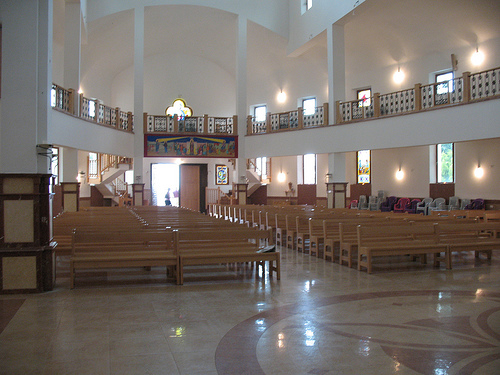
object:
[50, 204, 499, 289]
pew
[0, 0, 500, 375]
church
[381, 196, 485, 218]
chair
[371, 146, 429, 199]
wall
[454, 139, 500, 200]
wall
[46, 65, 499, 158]
balcony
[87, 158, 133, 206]
stairs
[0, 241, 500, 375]
floor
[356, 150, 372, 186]
window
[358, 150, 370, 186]
glass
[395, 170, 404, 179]
light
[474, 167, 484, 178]
light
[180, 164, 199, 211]
door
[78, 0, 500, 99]
ceiling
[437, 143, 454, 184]
glass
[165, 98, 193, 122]
window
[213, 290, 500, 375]
design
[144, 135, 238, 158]
painting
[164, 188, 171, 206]
person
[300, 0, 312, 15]
window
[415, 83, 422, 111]
column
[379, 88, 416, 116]
railing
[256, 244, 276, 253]
clothing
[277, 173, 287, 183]
light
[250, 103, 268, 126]
window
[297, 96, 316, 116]
window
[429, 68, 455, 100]
window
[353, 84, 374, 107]
window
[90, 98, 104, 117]
window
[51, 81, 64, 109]
window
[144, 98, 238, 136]
podium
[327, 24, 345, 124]
beam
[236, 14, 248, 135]
beam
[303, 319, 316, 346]
sunlight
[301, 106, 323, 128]
railing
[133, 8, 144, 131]
beam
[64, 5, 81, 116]
beam